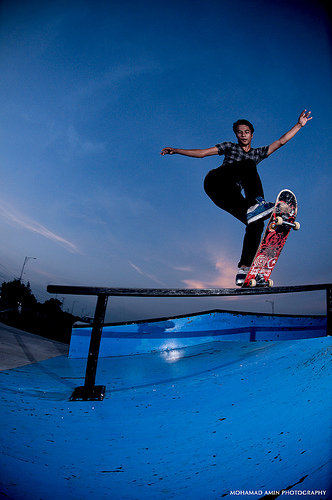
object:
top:
[215, 141, 270, 190]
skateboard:
[241, 188, 301, 289]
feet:
[246, 201, 275, 225]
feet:
[235, 266, 274, 287]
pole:
[19, 256, 27, 281]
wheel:
[275, 216, 283, 226]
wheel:
[293, 221, 301, 231]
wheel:
[268, 279, 274, 286]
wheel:
[249, 279, 257, 288]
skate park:
[0, 188, 332, 500]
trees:
[0, 279, 64, 341]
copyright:
[229, 489, 327, 497]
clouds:
[0, 185, 245, 301]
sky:
[0, 0, 332, 290]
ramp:
[0, 307, 332, 499]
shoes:
[235, 196, 276, 287]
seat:
[46, 283, 332, 401]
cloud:
[20, 107, 105, 167]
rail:
[46, 284, 332, 401]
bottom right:
[229, 488, 326, 496]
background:
[1, 222, 327, 360]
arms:
[178, 123, 298, 159]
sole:
[236, 283, 269, 287]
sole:
[249, 211, 273, 227]